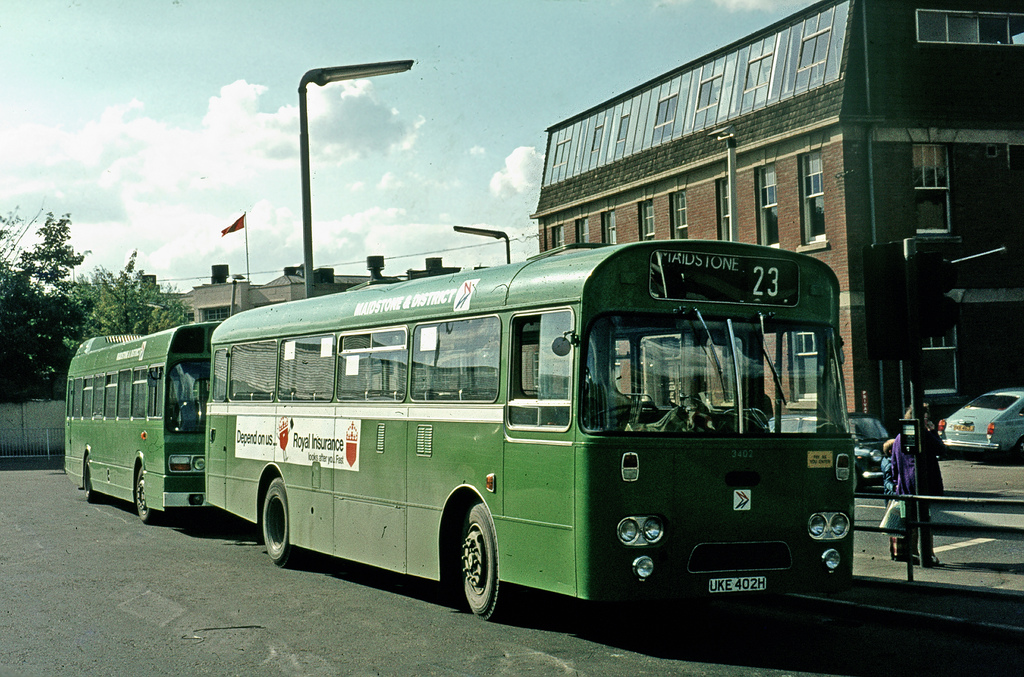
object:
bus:
[203, 239, 858, 618]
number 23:
[753, 266, 780, 297]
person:
[892, 401, 946, 566]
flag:
[221, 214, 246, 237]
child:
[881, 438, 897, 508]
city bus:
[65, 317, 215, 523]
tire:
[455, 502, 501, 621]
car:
[941, 388, 1024, 462]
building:
[528, 0, 1024, 458]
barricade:
[0, 427, 68, 460]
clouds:
[184, 79, 301, 200]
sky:
[0, 0, 813, 286]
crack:
[955, 617, 991, 632]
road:
[0, 451, 1024, 674]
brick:
[833, 216, 846, 220]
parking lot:
[941, 465, 1024, 494]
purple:
[892, 437, 946, 494]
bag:
[877, 500, 907, 532]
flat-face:
[577, 237, 857, 603]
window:
[799, 150, 823, 245]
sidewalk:
[922, 563, 1024, 593]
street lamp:
[298, 58, 418, 297]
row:
[539, 0, 856, 189]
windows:
[682, 0, 846, 133]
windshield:
[580, 314, 851, 437]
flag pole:
[244, 211, 250, 281]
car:
[851, 417, 890, 493]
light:
[309, 59, 415, 86]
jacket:
[892, 431, 946, 497]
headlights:
[618, 516, 667, 548]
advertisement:
[235, 415, 361, 473]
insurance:
[310, 434, 343, 451]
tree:
[0, 214, 80, 390]